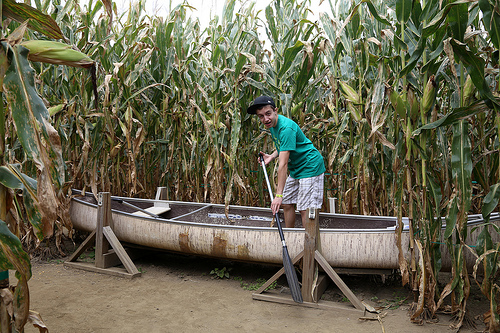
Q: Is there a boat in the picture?
A: Yes, there is a boat.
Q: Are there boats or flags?
A: Yes, there is a boat.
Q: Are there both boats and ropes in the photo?
A: No, there is a boat but no ropes.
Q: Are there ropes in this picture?
A: No, there are no ropes.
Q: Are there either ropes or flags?
A: No, there are no ropes or flags.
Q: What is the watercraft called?
A: The watercraft is a boat.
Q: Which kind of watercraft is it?
A: The watercraft is a boat.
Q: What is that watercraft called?
A: This is a boat.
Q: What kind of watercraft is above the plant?
A: The watercraft is a boat.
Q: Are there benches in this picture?
A: Yes, there is a bench.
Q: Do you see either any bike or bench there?
A: Yes, there is a bench.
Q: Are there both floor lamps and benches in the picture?
A: No, there is a bench but no floor lamps.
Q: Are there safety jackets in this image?
A: No, there are no safety jackets.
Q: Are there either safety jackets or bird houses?
A: No, there are no safety jackets or bird houses.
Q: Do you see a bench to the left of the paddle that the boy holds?
A: Yes, there is a bench to the left of the paddle.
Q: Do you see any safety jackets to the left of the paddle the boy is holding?
A: No, there is a bench to the left of the oar.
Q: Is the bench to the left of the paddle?
A: Yes, the bench is to the left of the paddle.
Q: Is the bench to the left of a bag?
A: No, the bench is to the left of the paddle.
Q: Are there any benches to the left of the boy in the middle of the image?
A: Yes, there is a bench to the left of the boy.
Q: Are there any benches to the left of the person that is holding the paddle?
A: Yes, there is a bench to the left of the boy.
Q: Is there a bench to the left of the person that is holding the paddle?
A: Yes, there is a bench to the left of the boy.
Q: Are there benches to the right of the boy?
A: No, the bench is to the left of the boy.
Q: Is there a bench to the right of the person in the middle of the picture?
A: No, the bench is to the left of the boy.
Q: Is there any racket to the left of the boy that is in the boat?
A: No, there is a bench to the left of the boy.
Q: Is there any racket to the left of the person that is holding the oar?
A: No, there is a bench to the left of the boy.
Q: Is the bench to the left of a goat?
A: No, the bench is to the left of a boy.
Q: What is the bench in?
A: The bench is in the boat.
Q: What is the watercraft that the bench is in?
A: The watercraft is a boat.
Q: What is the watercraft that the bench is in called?
A: The watercraft is a boat.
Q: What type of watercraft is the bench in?
A: The bench is in the boat.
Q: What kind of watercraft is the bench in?
A: The bench is in the boat.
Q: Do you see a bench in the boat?
A: Yes, there is a bench in the boat.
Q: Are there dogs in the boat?
A: No, there is a bench in the boat.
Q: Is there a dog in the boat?
A: No, there is a bench in the boat.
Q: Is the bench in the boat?
A: Yes, the bench is in the boat.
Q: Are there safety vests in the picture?
A: No, there are no safety vests.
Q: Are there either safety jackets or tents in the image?
A: No, there are no safety jackets or tents.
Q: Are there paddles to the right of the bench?
A: Yes, there is a paddle to the right of the bench.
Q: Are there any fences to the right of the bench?
A: No, there is a paddle to the right of the bench.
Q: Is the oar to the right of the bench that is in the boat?
A: Yes, the oar is to the right of the bench.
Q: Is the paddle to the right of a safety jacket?
A: No, the paddle is to the right of the bench.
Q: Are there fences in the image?
A: No, there are no fences.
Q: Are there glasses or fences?
A: No, there are no fences or glasses.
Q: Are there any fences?
A: No, there are no fences.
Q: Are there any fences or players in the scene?
A: No, there are no fences or players.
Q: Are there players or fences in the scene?
A: No, there are no fences or players.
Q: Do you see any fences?
A: No, there are no fences.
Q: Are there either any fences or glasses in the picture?
A: No, there are no fences or glasses.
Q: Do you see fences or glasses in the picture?
A: No, there are no fences or glasses.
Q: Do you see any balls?
A: No, there are no balls.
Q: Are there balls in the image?
A: No, there are no balls.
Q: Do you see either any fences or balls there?
A: No, there are no balls or fences.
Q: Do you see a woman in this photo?
A: No, there are no women.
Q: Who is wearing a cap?
A: The boy is wearing a cap.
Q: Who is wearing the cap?
A: The boy is wearing a cap.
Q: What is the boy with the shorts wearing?
A: The boy is wearing a cap.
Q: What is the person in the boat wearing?
A: The boy is wearing a cap.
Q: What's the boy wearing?
A: The boy is wearing a cap.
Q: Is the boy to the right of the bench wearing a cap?
A: Yes, the boy is wearing a cap.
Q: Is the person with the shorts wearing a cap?
A: Yes, the boy is wearing a cap.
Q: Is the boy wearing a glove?
A: No, the boy is wearing a cap.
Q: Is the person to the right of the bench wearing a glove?
A: No, the boy is wearing a cap.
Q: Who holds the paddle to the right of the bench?
A: The boy holds the paddle.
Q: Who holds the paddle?
A: The boy holds the paddle.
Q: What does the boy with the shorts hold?
A: The boy holds the oar.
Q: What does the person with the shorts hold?
A: The boy holds the oar.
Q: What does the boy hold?
A: The boy holds the oar.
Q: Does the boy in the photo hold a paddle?
A: Yes, the boy holds a paddle.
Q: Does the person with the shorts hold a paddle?
A: Yes, the boy holds a paddle.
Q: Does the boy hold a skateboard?
A: No, the boy holds a paddle.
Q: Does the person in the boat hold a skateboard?
A: No, the boy holds a paddle.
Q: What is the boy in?
A: The boy is in the boat.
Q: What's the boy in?
A: The boy is in the boat.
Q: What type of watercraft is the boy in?
A: The boy is in the boat.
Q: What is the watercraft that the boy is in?
A: The watercraft is a boat.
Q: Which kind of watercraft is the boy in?
A: The boy is in the boat.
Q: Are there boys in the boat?
A: Yes, there is a boy in the boat.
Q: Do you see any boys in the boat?
A: Yes, there is a boy in the boat.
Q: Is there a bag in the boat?
A: No, there is a boy in the boat.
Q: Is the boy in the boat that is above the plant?
A: Yes, the boy is in the boat.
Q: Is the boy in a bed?
A: No, the boy is in the boat.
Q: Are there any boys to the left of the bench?
A: No, the boy is to the right of the bench.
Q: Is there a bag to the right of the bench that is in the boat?
A: No, there is a boy to the right of the bench.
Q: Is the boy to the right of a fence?
A: No, the boy is to the right of the bench.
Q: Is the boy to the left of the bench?
A: No, the boy is to the right of the bench.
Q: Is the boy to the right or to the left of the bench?
A: The boy is to the right of the bench.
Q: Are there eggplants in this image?
A: No, there are no eggplants.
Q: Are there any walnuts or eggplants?
A: No, there are no eggplants or walnuts.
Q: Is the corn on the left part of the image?
A: Yes, the corn is on the left of the image.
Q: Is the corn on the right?
A: No, the corn is on the left of the image.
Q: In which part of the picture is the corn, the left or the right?
A: The corn is on the left of the image.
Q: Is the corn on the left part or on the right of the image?
A: The corn is on the left of the image.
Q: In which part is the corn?
A: The corn is on the left of the image.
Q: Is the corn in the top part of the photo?
A: Yes, the corn is in the top of the image.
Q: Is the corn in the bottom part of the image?
A: No, the corn is in the top of the image.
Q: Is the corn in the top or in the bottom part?
A: The corn is in the top of the image.